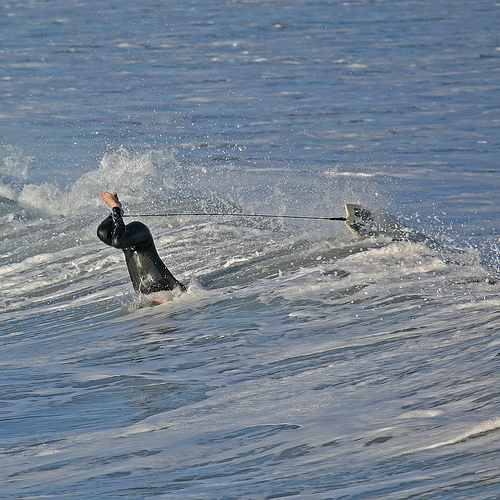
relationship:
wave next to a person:
[2, 194, 500, 401] [95, 190, 185, 293]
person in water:
[95, 190, 185, 293] [2, 1, 500, 500]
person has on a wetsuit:
[95, 190, 185, 293] [95, 209, 181, 292]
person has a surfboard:
[95, 190, 185, 293] [345, 204, 437, 243]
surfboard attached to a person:
[345, 204, 437, 243] [95, 190, 185, 293]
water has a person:
[2, 1, 500, 500] [95, 190, 185, 293]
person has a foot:
[95, 190, 185, 293] [102, 191, 119, 207]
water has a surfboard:
[2, 1, 500, 500] [345, 204, 437, 243]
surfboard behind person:
[345, 204, 437, 243] [95, 190, 185, 293]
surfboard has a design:
[345, 204, 437, 243] [352, 211, 375, 232]